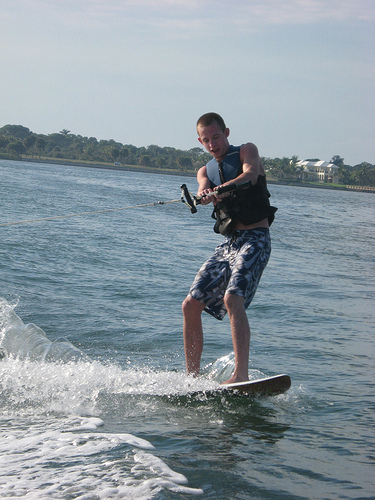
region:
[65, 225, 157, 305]
the water is calm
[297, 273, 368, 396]
the water is calm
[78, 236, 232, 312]
the water is calm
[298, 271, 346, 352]
the water is calm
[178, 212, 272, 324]
man is wearing shorts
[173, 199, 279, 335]
man is wearing shorts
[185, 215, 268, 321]
man is wearing shorts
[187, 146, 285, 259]
the life vest is gray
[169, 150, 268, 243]
the life vest is gray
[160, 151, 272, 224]
the life vest is gray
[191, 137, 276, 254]
the life vest is gray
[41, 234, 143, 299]
the water is calm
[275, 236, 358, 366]
the water is calm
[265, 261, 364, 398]
the water is calm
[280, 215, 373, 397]
the water is calm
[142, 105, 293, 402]
The man is wake boarding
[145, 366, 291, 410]
The board is white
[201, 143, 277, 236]
The man is wearing a blue and black vest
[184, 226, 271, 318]
The man is wearing blue shorts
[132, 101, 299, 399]
The man is holding onto a rope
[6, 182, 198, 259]
The rope is black and grey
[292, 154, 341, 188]
The house is white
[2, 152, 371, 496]
The water is dark blue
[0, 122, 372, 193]
Trees on the shore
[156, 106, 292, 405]
The man is riding the board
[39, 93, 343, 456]
man on standing on board in water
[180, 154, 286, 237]
man has blue vest on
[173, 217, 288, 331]
man wearing multi-print shorts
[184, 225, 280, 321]
shorts are blue and white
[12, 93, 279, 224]
man holding onto chord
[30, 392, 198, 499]
water has white foam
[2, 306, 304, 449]
board causing wave in water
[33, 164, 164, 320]
water is dark blue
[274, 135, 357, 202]
white building in distance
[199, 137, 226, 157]
man has mouth open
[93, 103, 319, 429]
Boy wakeboarding on lake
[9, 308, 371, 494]
Wake made by nearby speedboat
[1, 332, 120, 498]
White water kicked up by boat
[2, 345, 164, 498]
Foamy water from running nearby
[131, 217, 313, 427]
Lower half of man wakeboarding on water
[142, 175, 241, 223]
Grip on the handle of atheletic water sport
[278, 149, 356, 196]
Large house on shore of lake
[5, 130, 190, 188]
Dense trees on shore of lake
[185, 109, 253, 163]
Boy with round face and short hair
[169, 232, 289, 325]
Swimming shorts on boy